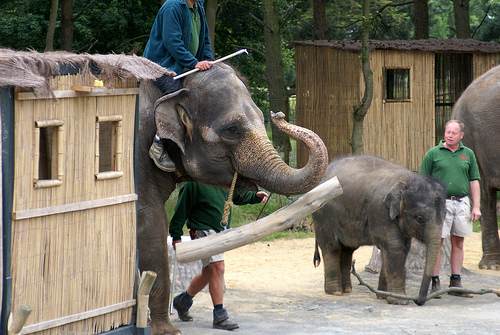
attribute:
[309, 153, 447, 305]
small elephant —  small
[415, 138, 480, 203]
shirt —  green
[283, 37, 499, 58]
roof —  thatched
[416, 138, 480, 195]
shirt —  green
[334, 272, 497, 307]
limb —  tree's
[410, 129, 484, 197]
shirt — green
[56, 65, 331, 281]
elephant — small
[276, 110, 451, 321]
elephant — with log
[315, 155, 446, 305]
baby elephant — a baby,   small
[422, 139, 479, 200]
shirt —  green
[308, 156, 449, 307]
elephant — a baby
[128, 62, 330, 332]
elephant —  large, large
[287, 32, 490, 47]
roof —  straw